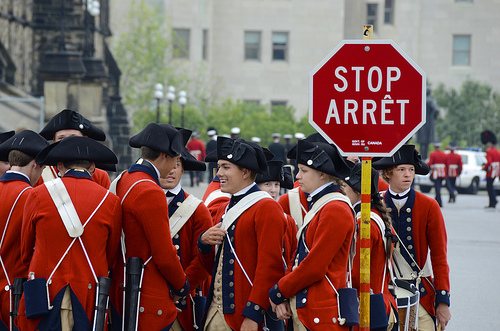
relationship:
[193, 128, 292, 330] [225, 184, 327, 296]
person in uniform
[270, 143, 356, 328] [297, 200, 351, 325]
person in uniform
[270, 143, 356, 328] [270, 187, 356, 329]
person wearing red jacket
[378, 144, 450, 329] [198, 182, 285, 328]
person wearing red jacket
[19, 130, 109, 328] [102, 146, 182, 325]
person wearing jacket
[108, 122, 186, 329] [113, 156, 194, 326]
person wearing jacket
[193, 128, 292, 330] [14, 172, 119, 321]
person wearing jacket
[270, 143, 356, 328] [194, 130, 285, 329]
person in uniform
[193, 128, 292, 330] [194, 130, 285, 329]
person in uniform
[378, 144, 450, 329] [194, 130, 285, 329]
person in uniform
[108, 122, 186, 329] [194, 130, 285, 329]
person in uniform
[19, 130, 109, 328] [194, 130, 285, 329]
person in uniform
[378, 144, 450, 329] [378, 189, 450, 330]
person wearing uniform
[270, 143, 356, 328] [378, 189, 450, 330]
person wearing uniform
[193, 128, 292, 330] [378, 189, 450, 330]
person wearing uniform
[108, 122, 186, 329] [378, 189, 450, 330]
person wearing uniform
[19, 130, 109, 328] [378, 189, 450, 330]
person wearing uniform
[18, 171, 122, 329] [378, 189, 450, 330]
red jacket wearing uniform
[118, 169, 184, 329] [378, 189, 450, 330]
uniform wearing uniform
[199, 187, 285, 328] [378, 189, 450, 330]
uniform wearing uniform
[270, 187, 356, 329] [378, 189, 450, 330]
red jacket wearing uniform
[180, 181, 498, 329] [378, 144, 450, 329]
street next to person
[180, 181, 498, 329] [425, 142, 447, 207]
street next to person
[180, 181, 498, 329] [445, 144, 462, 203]
street next to person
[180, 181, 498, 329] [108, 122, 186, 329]
street next to person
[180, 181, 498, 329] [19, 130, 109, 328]
street next to person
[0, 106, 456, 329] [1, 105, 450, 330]
group of soldiers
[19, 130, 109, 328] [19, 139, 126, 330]
person in uniform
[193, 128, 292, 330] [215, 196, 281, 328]
person wearing red jacket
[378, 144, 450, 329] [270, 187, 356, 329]
person wearing red jacket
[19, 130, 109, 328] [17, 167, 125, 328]
person wearing jacket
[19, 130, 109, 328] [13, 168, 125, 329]
person in uniform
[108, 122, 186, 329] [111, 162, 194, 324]
person in uniform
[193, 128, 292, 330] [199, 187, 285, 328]
person in uniform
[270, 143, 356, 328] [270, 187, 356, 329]
person in red jacket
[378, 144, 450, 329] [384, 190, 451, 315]
person in red jacket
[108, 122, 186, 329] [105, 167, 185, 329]
person wearing red jacket